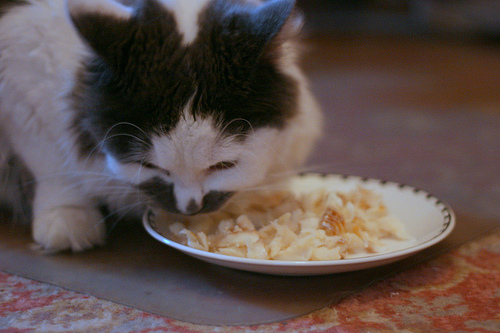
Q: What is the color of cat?
A: White.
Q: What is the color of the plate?
A: White.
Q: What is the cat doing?
A: Eating.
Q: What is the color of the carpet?
A: Red.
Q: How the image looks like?
A: Good.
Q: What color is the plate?
A: White.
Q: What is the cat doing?
A: Eating.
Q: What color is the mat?
A: Brown.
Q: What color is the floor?
A: Red.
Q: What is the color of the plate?
A: White.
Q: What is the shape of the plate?
A: Circle.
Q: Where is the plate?
A: On the ground.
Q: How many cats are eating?
A: One.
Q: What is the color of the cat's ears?
A: Black.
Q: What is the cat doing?
A: Eating.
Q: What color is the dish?
A: White with a brown trim.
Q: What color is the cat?
A: White and black.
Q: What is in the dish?
A: Cat food.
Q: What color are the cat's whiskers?
A: Whites.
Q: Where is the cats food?
A: On the plate.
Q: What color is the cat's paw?
A: White.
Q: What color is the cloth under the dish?
A: Red paisley.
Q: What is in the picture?
A: A cat.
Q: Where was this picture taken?
A: In the kitchen.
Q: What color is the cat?
A: Black and white.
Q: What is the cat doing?
A: Eating.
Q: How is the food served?
A: A plate.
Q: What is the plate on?
A: A placemat.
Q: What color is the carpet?
A: Red.